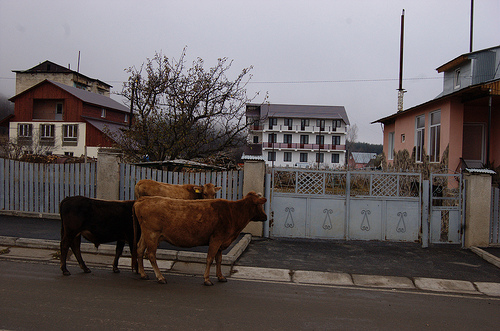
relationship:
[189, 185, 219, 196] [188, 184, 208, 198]
tag in ear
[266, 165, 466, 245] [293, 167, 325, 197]
gate with latticework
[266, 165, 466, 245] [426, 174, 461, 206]
gate with curlicues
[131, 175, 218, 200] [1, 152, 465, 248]
cow by fencing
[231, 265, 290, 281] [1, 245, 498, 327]
square on street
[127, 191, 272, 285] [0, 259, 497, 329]
cow on street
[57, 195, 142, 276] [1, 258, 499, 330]
cow on street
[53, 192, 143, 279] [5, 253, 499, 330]
cow on street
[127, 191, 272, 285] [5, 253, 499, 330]
cow on street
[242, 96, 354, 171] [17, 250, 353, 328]
white house on street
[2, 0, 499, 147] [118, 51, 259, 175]
sky over trees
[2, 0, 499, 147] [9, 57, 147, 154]
sky over house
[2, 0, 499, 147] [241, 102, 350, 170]
sky over white house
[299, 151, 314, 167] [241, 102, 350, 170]
window on white house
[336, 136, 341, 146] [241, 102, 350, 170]
window on white house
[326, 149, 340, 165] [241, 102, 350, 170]
window on white house